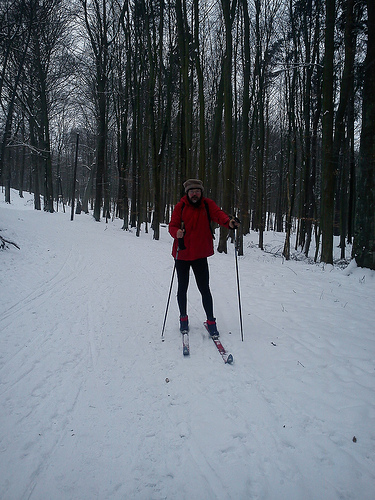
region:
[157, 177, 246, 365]
Man cross-country skiing.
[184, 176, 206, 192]
WInter hat on man's head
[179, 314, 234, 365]
Cross-country skis on man's feet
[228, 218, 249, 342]
Ski pole in man's hand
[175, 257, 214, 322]
Black tights on man's legs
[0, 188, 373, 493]
Snow covering the ground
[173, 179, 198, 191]
person has brown cap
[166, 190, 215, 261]
person has red coat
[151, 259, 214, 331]
person has black pants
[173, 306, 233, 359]
person has black shoes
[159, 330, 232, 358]
person on red skis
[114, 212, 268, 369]
person is holding poles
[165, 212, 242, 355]
two black poles in snow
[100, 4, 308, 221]
tall and bare trees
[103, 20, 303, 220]
tall trees behind person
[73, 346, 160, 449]
white snow on ground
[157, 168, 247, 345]
man with red coat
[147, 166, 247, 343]
man holding two poles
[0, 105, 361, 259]
man in front trunks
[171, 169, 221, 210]
beanie is color brown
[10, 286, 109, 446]
marks of skis on the snow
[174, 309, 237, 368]
skies are long and narrow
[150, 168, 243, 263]
man wearing glasses on face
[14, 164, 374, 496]
man in an open field with snow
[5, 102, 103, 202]
branches of trees without leaves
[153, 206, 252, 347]
snow poles are long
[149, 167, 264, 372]
A man skiing on ice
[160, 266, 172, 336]
Skiing pole in the hands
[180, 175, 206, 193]
A hat in the head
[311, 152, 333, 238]
Tree trunk in the forest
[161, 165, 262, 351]
A man skiing alone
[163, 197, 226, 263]
the jacket is red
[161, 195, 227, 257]
the jacket is red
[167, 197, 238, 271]
the jacket is red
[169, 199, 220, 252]
the jacket is red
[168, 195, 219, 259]
the jacket is red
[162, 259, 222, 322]
the leggings are black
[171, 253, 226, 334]
the leggings are black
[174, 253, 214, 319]
the leggings are black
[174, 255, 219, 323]
the leggings are black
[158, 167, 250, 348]
a person with red coat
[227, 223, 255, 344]
a pole on right side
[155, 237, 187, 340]
pole on left side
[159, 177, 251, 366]
man wearing red jacket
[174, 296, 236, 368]
skis in the snow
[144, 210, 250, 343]
ski poles the man is holding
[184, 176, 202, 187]
hat the man is wearing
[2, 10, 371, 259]
trees behind the man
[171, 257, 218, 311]
black pants the man is wearing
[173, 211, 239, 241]
handles on the ski poles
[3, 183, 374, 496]
snow the man is skiing on